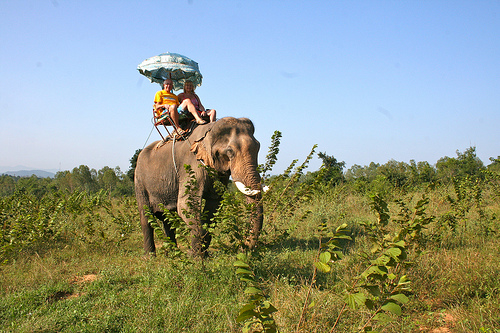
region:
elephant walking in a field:
[87, 102, 319, 295]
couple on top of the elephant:
[105, 28, 269, 170]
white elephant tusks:
[219, 157, 273, 212]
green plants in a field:
[273, 118, 444, 270]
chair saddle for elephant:
[155, 112, 187, 158]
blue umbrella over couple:
[134, 28, 210, 78]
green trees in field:
[61, 157, 107, 190]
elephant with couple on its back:
[92, 30, 310, 262]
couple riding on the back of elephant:
[95, 47, 321, 327]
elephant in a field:
[49, 35, 303, 327]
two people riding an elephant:
[120, 48, 267, 264]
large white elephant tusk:
[232, 178, 262, 198]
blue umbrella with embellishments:
[134, 48, 204, 85]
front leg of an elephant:
[180, 178, 213, 255]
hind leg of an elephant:
[138, 185, 153, 262]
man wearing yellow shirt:
[154, 80, 204, 137]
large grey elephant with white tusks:
[132, 115, 267, 257]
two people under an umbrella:
[137, 48, 214, 144]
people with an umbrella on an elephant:
[121, 45, 275, 260]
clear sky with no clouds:
[7, 1, 498, 169]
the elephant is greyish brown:
[139, 130, 289, 255]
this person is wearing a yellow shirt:
[151, 75, 181, 106]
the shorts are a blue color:
[155, 105, 202, 125]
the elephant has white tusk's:
[226, 170, 308, 218]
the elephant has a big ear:
[183, 120, 220, 176]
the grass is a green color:
[118, 278, 238, 323]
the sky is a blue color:
[318, 13, 485, 96]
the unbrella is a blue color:
[130, 45, 224, 86]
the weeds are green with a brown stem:
[302, 202, 460, 326]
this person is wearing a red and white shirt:
[178, 78, 205, 107]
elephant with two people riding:
[131, 42, 272, 259]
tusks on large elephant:
[231, 170, 276, 207]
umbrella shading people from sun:
[127, 35, 225, 140]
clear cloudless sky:
[2, 6, 492, 183]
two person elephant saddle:
[150, 100, 211, 165]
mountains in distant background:
[2, 155, 87, 187]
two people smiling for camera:
[152, 72, 214, 127]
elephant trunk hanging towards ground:
[229, 127, 272, 264]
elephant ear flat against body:
[186, 120, 231, 178]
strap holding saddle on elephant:
[164, 132, 185, 183]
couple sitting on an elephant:
[155, 79, 211, 135]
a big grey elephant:
[134, 117, 270, 254]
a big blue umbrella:
[137, 51, 198, 78]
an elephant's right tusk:
[233, 178, 258, 197]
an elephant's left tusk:
[262, 181, 274, 193]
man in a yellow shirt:
[155, 79, 205, 137]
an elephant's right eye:
[223, 143, 235, 160]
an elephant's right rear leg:
[132, 162, 157, 251]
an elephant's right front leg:
[175, 176, 207, 256]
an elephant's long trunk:
[229, 166, 263, 246]